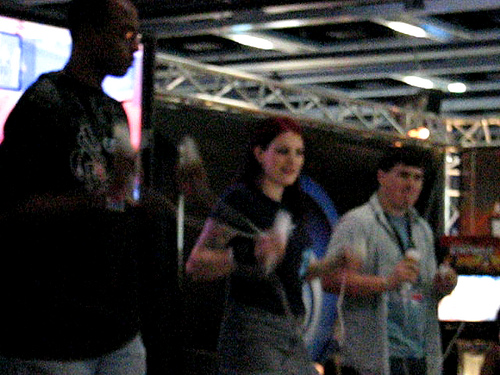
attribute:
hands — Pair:
[334, 248, 457, 305]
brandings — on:
[69, 99, 147, 222]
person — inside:
[319, 142, 462, 373]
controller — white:
[397, 245, 423, 297]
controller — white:
[256, 205, 303, 285]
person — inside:
[247, 113, 322, 361]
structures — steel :
[233, 14, 420, 120]